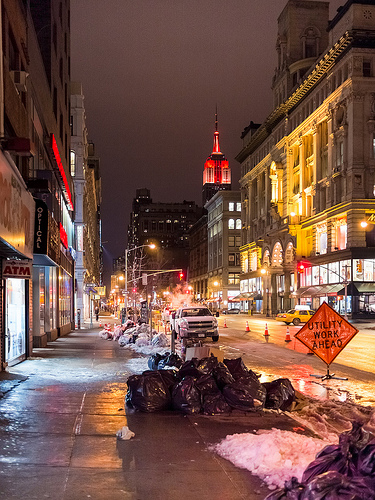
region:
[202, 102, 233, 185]
top of a building lit up in red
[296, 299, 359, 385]
an orange construction sign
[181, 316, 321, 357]
a row of orange traffic cones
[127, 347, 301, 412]
a pile of black trashbags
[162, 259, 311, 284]
a pair of red traffic lights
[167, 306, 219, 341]
a white and chrome pickup truck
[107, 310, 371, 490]
wintery mix on sidewalk and street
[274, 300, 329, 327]
a yellow four door taxi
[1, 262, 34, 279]
a small white sign reading "ATM" in red letters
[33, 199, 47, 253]
side of a black awning reading "Optical" in whtie letters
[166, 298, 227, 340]
white pick up parked on street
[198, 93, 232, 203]
tall building with red light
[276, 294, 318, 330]
yellow cab traveling down street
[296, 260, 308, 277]
traffic light on red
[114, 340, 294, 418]
black trash bags on curb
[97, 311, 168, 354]
white trash bags on curb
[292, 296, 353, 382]
orange sign in street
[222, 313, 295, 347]
cones in the road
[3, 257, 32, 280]
white sign on building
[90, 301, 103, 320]
man walking down sidewalk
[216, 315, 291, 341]
Orange and white cones.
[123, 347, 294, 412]
A pile of black bags of trash.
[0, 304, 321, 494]
The sidewalk.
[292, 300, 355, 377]
An orange and black street sign.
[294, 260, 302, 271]
A traffic light displaying a red light.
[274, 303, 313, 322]
A yellow taxi cab.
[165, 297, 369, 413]
The street.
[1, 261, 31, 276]
A red and white ATM sign.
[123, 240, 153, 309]
A street light lit up.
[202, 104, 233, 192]
The top of a building lit up red.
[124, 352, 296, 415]
the trash is on the sidewalk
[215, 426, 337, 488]
the sidewalk has snow on it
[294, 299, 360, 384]
utility work ahead on road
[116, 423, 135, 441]
someone littered on the sidewalk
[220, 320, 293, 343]
there are four cones on the road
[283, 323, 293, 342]
the cone is orange and white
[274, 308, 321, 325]
the cab is yellow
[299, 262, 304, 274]
the light is red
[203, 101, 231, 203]
the building is lit up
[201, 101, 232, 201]
the lights are red and white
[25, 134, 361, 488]
a city street at night during winter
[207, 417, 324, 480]
snow that has not yet melted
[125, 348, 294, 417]
trash that has yet to be collected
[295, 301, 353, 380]
utility work caution sign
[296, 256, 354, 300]
traffic light that is lit up red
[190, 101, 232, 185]
a building in the distance with red lighting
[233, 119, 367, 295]
a building with yellow lighting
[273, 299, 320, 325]
a yellow taxi cab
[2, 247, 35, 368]
a lit store front with an ATM sign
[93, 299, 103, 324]
a person walking down the sidewalk